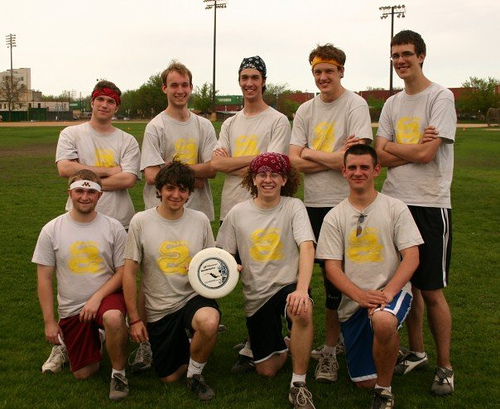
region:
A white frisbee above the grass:
[189, 245, 236, 295]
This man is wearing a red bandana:
[249, 153, 284, 171]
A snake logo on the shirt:
[157, 240, 192, 270]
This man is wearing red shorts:
[56, 297, 131, 364]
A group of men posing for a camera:
[37, 32, 457, 407]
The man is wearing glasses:
[390, 50, 419, 60]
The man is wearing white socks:
[186, 359, 203, 376]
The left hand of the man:
[287, 285, 304, 308]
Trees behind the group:
[112, 71, 216, 116]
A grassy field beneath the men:
[3, 128, 498, 407]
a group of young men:
[26, 22, 467, 389]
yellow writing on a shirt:
[241, 226, 296, 281]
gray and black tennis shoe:
[186, 368, 216, 402]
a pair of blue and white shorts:
[346, 283, 414, 381]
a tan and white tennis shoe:
[425, 361, 462, 394]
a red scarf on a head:
[251, 154, 292, 181]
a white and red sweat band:
[66, 179, 103, 189]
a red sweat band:
[91, 86, 128, 104]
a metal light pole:
[199, 1, 229, 107]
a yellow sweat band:
[311, 51, 346, 72]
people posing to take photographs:
[67, 68, 459, 406]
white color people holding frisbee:
[188, 237, 246, 305]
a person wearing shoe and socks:
[291, 369, 309, 406]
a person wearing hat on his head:
[64, 165, 111, 194]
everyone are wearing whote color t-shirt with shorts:
[34, 129, 467, 304]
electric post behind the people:
[201, 3, 232, 112]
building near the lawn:
[1, 65, 70, 122]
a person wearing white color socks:
[183, 360, 221, 378]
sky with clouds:
[53, 2, 219, 54]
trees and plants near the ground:
[130, 83, 155, 107]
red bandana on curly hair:
[236, 145, 299, 202]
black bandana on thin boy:
[228, 43, 279, 107]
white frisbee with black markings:
[186, 243, 247, 305]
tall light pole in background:
[3, 29, 21, 117]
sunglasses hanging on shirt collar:
[349, 194, 403, 267]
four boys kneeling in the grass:
[33, 137, 482, 407]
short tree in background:
[454, 62, 497, 134]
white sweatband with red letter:
[68, 173, 110, 209]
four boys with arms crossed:
[34, 30, 488, 172]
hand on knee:
[273, 215, 331, 405]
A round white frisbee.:
[189, 247, 238, 298]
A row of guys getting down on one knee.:
[28, 150, 425, 407]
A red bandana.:
[249, 148, 291, 175]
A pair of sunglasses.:
[354, 210, 369, 238]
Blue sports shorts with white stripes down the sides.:
[339, 288, 414, 380]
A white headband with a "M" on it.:
[66, 180, 103, 192]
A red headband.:
[84, 85, 124, 104]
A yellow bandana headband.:
[307, 54, 347, 69]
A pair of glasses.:
[388, 52, 423, 61]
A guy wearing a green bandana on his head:
[217, 55, 296, 229]